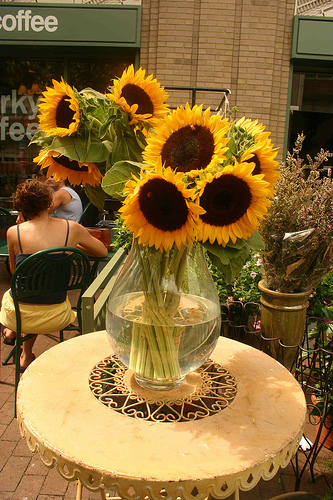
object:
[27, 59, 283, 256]
sunflowers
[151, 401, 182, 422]
heart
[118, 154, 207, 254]
flower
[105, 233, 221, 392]
vase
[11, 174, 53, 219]
head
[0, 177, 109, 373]
person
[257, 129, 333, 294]
flower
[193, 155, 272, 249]
flower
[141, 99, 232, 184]
flower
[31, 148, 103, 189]
flower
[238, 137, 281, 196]
flower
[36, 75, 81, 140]
flower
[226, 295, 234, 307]
flower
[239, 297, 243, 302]
flower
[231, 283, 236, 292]
flower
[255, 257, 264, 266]
flower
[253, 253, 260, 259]
flower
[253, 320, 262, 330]
flower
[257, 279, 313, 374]
vase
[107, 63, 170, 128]
flower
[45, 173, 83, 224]
man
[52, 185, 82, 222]
shirt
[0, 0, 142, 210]
shop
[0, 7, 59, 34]
letters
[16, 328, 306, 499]
table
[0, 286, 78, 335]
skirt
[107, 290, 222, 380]
water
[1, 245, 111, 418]
chair